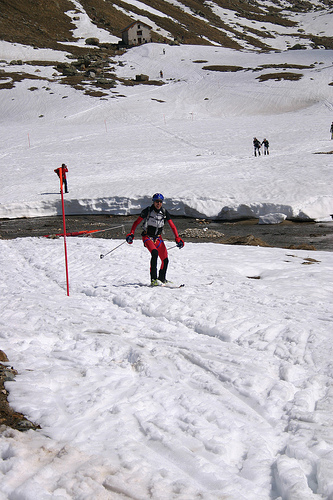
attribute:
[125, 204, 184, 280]
clothing — red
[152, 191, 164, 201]
helmet — blue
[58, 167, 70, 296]
pole — red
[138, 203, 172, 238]
top — black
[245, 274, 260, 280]
spot — bare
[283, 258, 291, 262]
spot — bare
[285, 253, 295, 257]
spot — bare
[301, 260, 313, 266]
spot — bare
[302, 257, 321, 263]
spot — bare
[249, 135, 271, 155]
two people — holding hands, in the distance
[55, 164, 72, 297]
red pole — sticking out of the snow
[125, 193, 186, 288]
man — in red and black suit skiing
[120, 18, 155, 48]
stone house — in the distance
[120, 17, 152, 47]
gray house — on the slope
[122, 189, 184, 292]
person — skiing down a slope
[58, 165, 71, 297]
red pole — in the snow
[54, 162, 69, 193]
man — in red jacket, taking pictures, in the distance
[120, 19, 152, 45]
house structure — in the distance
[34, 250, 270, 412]
snow — wide swath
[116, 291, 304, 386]
patterns — in the snow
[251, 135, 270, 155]
skiers — in the background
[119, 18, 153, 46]
building — in the background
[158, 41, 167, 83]
skiers — leaving the building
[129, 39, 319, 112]
snow drifts — on the hillside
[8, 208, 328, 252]
river — icy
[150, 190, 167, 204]
helmet — blue, safety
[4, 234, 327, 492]
snow — dirty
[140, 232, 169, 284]
pants — red, snow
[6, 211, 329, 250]
stream — small